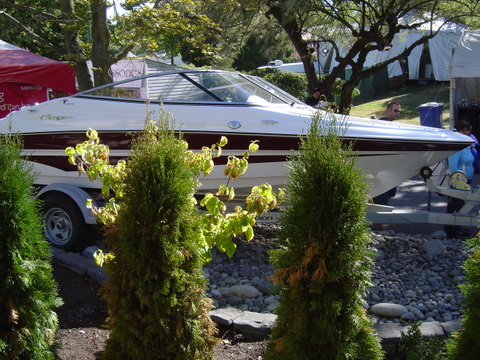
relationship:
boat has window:
[1, 69, 475, 250] [91, 69, 302, 102]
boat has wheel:
[1, 69, 475, 250] [31, 185, 94, 266]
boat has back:
[1, 69, 479, 222] [0, 88, 70, 185]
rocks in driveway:
[373, 232, 445, 308] [9, 175, 476, 348]